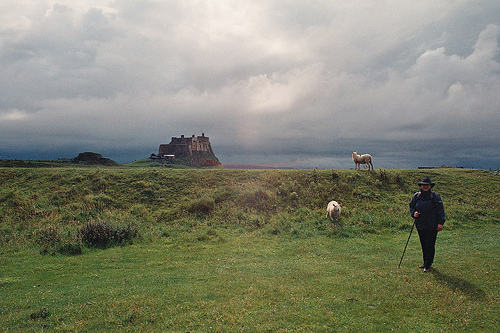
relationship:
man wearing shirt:
[409, 178, 445, 273] [407, 190, 444, 222]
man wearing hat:
[409, 178, 445, 273] [407, 174, 436, 188]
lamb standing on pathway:
[351, 151, 373, 170] [2, 164, 349, 171]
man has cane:
[409, 178, 445, 273] [398, 220, 416, 268]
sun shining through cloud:
[205, 6, 289, 104] [0, 0, 499, 153]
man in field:
[409, 178, 445, 273] [1, 165, 498, 332]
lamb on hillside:
[321, 199, 352, 233] [3, 165, 492, 329]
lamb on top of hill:
[349, 146, 376, 172] [5, 158, 492, 234]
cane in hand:
[396, 220, 415, 272] [411, 208, 423, 221]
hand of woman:
[411, 208, 423, 221] [405, 170, 452, 269]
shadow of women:
[430, 264, 490, 304] [408, 177, 438, 269]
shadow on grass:
[430, 264, 490, 304] [0, 164, 471, 323]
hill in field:
[70, 151, 120, 167] [3, 160, 484, 313]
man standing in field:
[409, 178, 445, 273] [7, 209, 499, 331]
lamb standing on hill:
[351, 151, 373, 170] [1, 163, 479, 248]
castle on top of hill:
[159, 130, 221, 167] [132, 152, 224, 168]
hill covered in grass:
[10, 171, 494, 241] [7, 166, 484, 259]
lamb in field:
[326, 201, 341, 220] [0, 221, 500, 331]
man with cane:
[406, 173, 448, 273] [392, 208, 416, 280]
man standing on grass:
[409, 178, 445, 273] [0, 164, 471, 323]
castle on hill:
[158, 133, 221, 166] [121, 159, 223, 169]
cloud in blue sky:
[0, 0, 499, 153] [0, 0, 498, 169]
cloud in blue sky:
[263, 21, 499, 154] [0, 0, 498, 169]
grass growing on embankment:
[254, 220, 312, 242] [7, 136, 473, 333]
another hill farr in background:
[60, 78, 155, 193] [20, 130, 497, 233]